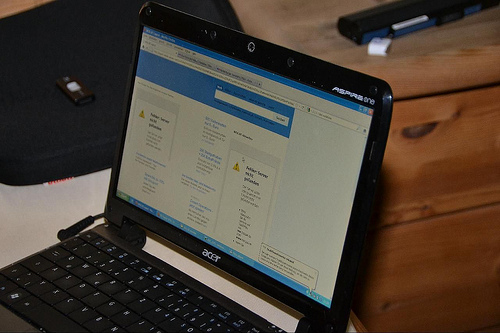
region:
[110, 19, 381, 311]
the monitor is turned on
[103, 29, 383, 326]
the monitor is turned on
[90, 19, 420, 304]
the monitor is turned on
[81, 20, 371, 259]
the monitor is turned on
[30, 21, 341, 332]
the laptop is black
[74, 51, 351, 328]
the laptop is black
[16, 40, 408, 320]
the laptop is black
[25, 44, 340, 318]
the laptop is black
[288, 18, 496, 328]
a dresser behind the laptop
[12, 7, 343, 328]
a black laptop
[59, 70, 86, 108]
a flash drive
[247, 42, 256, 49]
the webcam on the laptop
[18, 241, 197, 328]
the keyboard on the computer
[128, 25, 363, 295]
the screen of the computer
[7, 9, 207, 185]
a black bag on the bed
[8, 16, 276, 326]
a bed under the laptop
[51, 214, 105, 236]
the charger of the laptop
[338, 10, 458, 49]
a charger on the desk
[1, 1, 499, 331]
laptop in front of wooden drawers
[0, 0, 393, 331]
laptop shows Acer name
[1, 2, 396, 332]
black bag behind laptop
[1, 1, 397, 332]
laptop is on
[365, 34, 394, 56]
small square white object atop wooden furniture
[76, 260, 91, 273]
white W on black key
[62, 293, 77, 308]
white C on black key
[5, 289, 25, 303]
windows symbol on black key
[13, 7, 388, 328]
the laptop is open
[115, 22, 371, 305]
the screen is on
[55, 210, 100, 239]
the computer's power cord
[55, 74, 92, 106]
a memory stick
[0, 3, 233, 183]
a black laptop case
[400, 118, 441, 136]
a knot on the table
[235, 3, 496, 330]
the table is wood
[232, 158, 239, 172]
caution symbol on the screen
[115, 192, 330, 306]
toolbar on the screen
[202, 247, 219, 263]
the computer brand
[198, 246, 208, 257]
letter a on laptop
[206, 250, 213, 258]
letter c on laptop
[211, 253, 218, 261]
letter e on laptop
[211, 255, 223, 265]
letter r on laptop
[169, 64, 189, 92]
blue on laptop screen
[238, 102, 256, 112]
white box on laptop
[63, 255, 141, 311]
keys on black keyboard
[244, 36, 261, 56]
camera on top laptop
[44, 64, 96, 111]
black usb for laptop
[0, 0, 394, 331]
the laptop is black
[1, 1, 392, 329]
the laptop is opened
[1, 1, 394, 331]
the laptop is turned on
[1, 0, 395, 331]
the keyboard on the laptop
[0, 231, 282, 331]
the keys on the keyboard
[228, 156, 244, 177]
warning icon of black exclamation mark on yellow triangle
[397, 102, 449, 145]
tear drop blemish on wood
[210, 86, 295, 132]
white search input field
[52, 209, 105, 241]
AC adapter power cord connector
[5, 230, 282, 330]
small black laptop keyboard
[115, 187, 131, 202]
green start button for Microsoft's Windows XP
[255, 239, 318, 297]
yellow information notification bubble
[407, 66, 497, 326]
natural unpainted wood table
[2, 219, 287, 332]
The keyboard of a laptop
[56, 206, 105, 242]
A small light attached to a laptop